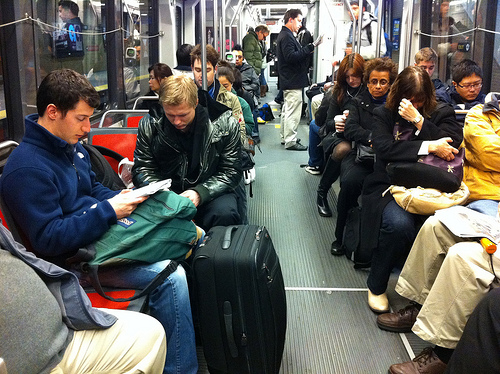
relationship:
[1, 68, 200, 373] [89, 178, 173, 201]
man reading paper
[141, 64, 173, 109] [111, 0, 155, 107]
woman looking out window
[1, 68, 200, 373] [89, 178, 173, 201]
man reading magazine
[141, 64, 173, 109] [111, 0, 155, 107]
woman watching out window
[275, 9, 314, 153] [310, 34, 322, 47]
man reading paper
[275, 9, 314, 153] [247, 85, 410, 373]
man standing in aisle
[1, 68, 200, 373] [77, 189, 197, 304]
man has backpack